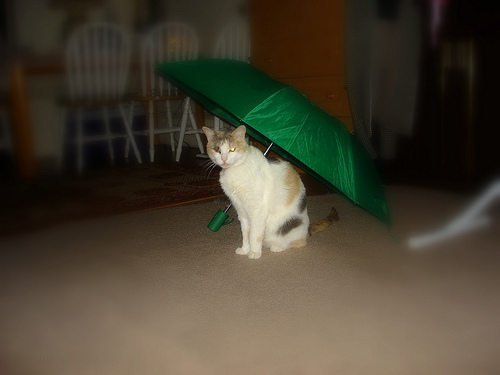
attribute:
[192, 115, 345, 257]
cat — white, sitting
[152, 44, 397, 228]
umbrella — green, collapsible, open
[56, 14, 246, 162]
chairs — white, wooden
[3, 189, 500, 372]
rug — beige, patterned, tan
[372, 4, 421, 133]
jacket — gray, hanging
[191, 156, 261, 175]
whiskers — white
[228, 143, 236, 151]
eye — yellow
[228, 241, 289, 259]
paws — white